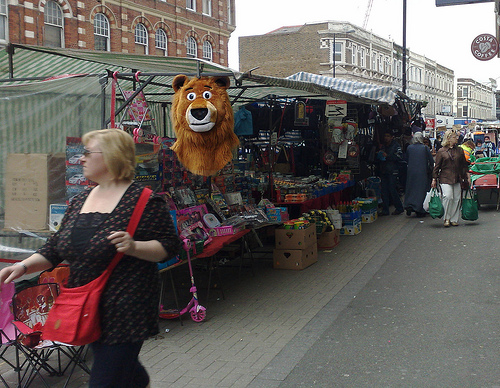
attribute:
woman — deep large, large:
[0, 125, 178, 384]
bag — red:
[23, 182, 155, 353]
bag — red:
[33, 186, 153, 346]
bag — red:
[37, 183, 156, 352]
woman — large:
[14, 126, 183, 386]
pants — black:
[81, 341, 152, 385]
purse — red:
[40, 185, 152, 340]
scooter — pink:
[164, 230, 210, 320]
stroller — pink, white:
[105, 69, 163, 151]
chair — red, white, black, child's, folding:
[8, 279, 62, 385]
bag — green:
[426, 191, 444, 217]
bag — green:
[459, 194, 479, 221]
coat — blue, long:
[402, 139, 434, 215]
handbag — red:
[34, 260, 112, 342]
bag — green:
[458, 192, 480, 226]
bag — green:
[422, 187, 446, 218]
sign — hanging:
[476, 37, 484, 45]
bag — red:
[53, 292, 98, 348]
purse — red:
[49, 292, 100, 348]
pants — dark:
[101, 354, 151, 385]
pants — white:
[441, 185, 467, 225]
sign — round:
[476, 38, 484, 52]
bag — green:
[459, 188, 482, 221]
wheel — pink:
[191, 304, 209, 323]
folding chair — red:
[15, 291, 50, 323]